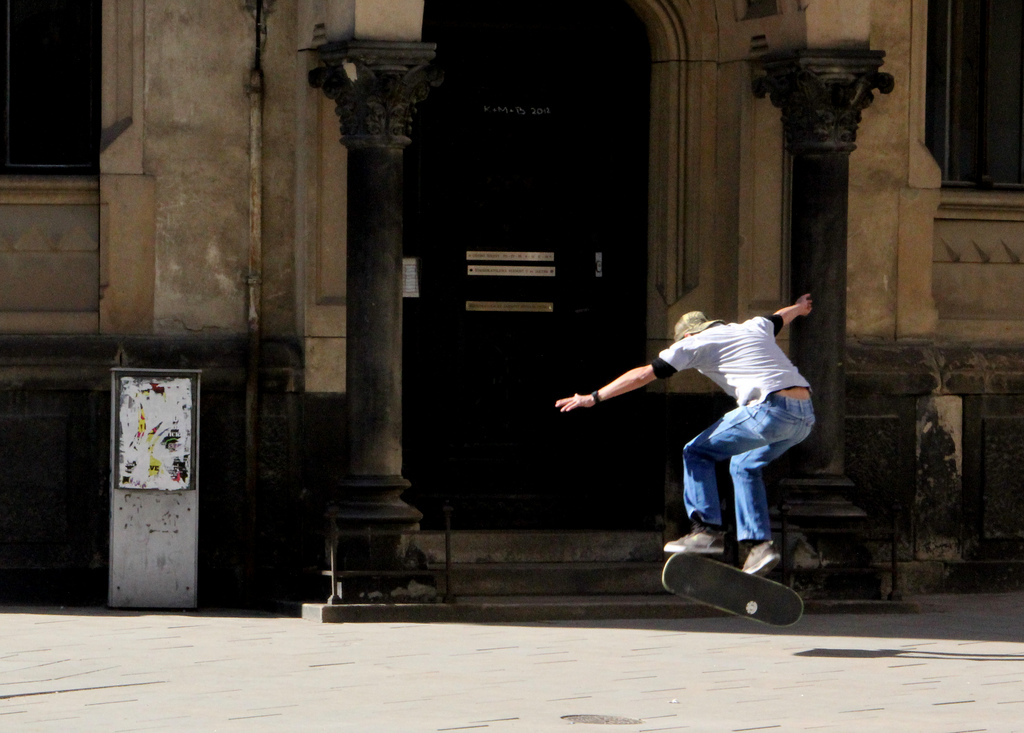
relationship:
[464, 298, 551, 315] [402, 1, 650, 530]
name plate on door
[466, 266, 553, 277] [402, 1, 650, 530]
name plate on door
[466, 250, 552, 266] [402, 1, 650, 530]
name plate on door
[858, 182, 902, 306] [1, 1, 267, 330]
stone in wall